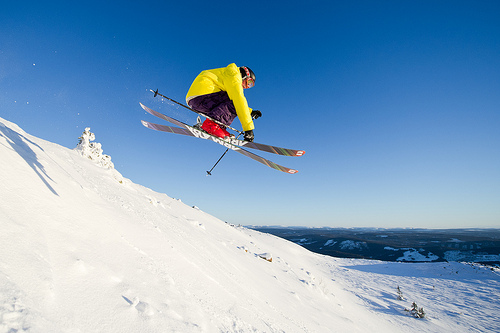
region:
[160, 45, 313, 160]
A man skiing on snow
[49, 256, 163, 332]
A ground covered by snow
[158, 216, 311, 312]
A ground covered by snow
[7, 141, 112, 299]
A ground covered by snow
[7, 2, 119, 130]
A clear blue sky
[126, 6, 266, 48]
A clear blue sky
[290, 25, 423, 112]
A clear blue sky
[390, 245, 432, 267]
A hill covered by snow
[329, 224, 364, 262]
A hill covered by snow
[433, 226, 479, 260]
A hill covered by snow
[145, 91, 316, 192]
skis are crossed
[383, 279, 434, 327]
threes at the bottom of the slope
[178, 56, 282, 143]
skier has a yellow jacket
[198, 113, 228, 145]
red ski boots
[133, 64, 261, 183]
skier is holding ski poles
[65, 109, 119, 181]
tree at the top of the slope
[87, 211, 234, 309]
snow on the slope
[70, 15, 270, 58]
sky is blue and clear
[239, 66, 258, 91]
skier has on goggles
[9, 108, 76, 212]
shadow in the snow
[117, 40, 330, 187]
the person on the skis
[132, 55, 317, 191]
the person is skiing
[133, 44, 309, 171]
the person going down the slope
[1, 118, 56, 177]
the shadow on the snow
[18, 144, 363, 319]
snow on the slope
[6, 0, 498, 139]
the sky is blue and clear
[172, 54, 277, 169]
the person holding ski poles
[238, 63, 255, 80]
person wearing goggles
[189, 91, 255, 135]
person wearing purple ski pants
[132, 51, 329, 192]
skier in the air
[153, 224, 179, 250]
patch of white snow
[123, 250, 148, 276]
patch of white snow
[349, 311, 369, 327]
patch of white snow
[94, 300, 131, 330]
patch of white snow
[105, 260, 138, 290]
patch of white snow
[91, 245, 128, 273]
patch of white snow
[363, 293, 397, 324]
patch of white snow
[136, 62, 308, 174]
Skiier in a yellow jacket, purple pants, and red shoes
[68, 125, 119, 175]
Snow covered tree on the side of a hill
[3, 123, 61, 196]
Shadow of man skiing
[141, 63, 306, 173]
Man in red shoes in mid-air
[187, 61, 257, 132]
Man's yellow ski jacket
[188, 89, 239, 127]
Men's purple ski pants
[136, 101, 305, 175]
Skis with a decorative design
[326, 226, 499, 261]
Barren snow covered landscape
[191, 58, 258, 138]
man wearing a yellow jacket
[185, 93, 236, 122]
man wearing purple pants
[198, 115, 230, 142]
man wearing red boots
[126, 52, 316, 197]
man in the air on skis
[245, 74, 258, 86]
man wearing snow goggles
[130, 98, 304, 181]
man on skis in the air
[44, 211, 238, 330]
snow on the ground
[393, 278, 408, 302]
tree growing out the snow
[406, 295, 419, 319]
tree growing out the snow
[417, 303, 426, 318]
tree growing out the snow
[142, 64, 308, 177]
the skier is in the air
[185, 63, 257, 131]
the jacket is yellow in color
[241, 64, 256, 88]
the man is wearing goggles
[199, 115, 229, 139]
the boots are red in color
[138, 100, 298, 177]
the skis are made of metal